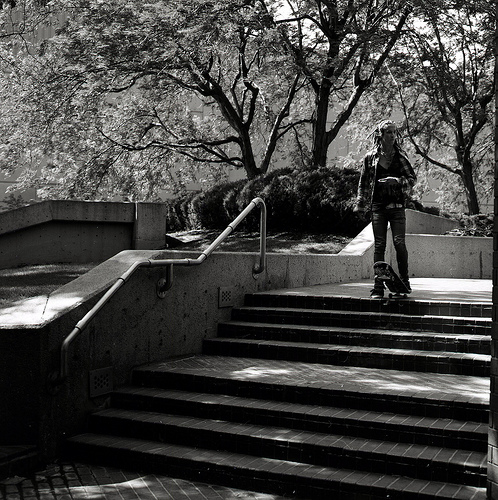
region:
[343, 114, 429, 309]
a kater on border of stairs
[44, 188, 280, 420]
a rail on side stairs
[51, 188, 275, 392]
a rail of metal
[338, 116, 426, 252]
man wears a squared shirt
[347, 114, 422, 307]
boy holds a skater with left feet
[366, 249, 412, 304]
skater is color black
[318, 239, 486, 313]
shadows on the ground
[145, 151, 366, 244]
bushes on side the stairs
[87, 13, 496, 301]
trees behind a boy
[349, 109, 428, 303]
boy looking to the right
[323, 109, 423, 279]
the person is standing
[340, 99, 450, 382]
the person is standing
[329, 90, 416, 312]
a woman with skateboard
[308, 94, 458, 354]
a woman with skateboard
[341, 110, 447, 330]
a person with skateboard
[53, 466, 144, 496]
the floor is tiled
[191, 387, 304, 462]
the floor is tiled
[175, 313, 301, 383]
the floor is tiled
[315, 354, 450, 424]
the floor is tiled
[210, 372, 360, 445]
the floor is tiled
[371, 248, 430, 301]
the foot is holding the skateboard up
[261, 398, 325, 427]
the steps are made of bricks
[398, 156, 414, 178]
the shirt is plaid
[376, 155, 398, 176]
the shirt is v cut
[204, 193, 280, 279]
the pipe is bent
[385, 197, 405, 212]
the person ia wearing a belt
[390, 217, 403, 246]
the pants are a dark color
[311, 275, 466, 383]
the trees are making shadows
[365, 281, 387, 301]
the person is wearing shoes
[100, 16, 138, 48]
the trees have leaves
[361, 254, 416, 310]
Skateboard is tilted back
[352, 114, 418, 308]
Girl is standing on skateboard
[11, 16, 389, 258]
Shade provided by trees in background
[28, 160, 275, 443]
Railing on side of stairway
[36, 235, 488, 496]
Two sets of stairs sloping downwards.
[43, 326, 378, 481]
Stairs are made of bricks.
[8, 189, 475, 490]
Stairway is shaded by the trees in the area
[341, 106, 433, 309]
Girl is wearing a flannel shirt and jeans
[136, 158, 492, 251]
Bushes surround the trees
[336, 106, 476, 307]
Girl is looking to her left.